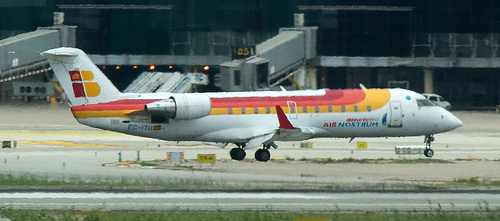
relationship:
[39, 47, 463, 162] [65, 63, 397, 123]
airplane has decorations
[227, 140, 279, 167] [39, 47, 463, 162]
back wheels of airplane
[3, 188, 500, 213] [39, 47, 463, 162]
road near airplane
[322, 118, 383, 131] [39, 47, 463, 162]
air nostrom owns airplane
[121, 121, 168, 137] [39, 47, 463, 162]
license plate of airplane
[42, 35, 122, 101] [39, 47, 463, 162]
tail of airplane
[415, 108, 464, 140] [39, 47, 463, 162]
nose of airplane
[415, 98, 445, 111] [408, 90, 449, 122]
windows of cockpit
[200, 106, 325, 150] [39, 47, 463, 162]
wing of airplane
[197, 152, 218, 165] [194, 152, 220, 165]
sign has black lettering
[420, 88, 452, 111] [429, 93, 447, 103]
car has dark windows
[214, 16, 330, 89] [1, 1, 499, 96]
boarding tunnel on building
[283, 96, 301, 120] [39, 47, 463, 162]
emergency door on airplane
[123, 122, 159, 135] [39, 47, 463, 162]
ec-itu on airplane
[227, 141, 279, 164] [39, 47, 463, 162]
wheels on airplane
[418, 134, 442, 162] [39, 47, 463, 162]
front wheel of airplane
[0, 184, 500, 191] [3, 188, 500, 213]
edge of road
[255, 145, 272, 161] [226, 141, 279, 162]
wheel of landing gear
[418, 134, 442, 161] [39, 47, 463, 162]
front landing gear on airplane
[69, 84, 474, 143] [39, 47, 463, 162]
fuselage of airplane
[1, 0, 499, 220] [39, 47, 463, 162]
picture of airplane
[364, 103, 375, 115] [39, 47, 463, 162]
window of airplane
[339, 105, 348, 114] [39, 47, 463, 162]
window of airplane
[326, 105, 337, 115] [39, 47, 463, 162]
window of airplane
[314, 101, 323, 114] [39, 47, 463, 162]
window of airplane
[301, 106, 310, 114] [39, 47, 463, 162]
window of airplane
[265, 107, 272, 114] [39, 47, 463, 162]
window on airplane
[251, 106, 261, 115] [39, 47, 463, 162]
window of airplane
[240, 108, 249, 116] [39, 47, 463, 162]
window of airplane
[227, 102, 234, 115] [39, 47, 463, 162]
window of airplane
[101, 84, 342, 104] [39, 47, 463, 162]
red stripe on airplane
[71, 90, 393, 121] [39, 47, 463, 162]
orange stripe on airplane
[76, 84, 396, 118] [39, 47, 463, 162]
yellow stripe on airplane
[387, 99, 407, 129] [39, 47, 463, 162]
door on airplane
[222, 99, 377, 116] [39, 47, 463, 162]
windows on airplane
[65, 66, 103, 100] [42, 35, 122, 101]
logo on tail